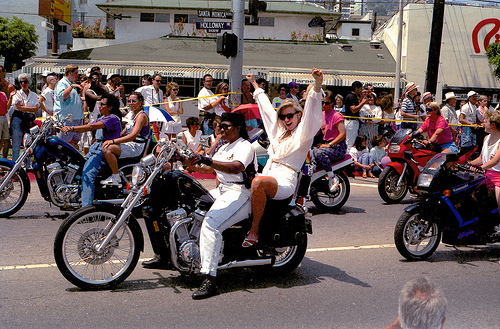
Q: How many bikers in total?
A: More than 10.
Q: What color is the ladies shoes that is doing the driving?
A: Black.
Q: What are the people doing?
A: Watching a parade.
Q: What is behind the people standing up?
A: Building.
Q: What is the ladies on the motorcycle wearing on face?
A: Sunglasses.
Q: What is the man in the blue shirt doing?
A: Watching the motorcycles go by.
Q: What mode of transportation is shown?
A: Motorcycles.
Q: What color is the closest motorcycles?
A: Black.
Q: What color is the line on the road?
A: White.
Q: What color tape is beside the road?
A: Yellow.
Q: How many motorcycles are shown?
A: 5.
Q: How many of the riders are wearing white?
A: 3.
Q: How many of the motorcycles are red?
A: 1.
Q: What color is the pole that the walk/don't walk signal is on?
A: Silver.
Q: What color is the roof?
A: Gray.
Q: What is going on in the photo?
A: Women riding motorcycles down a street.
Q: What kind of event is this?
A: A parade.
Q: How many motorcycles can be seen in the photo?
A: Five.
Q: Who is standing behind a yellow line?
A: People watching the parade.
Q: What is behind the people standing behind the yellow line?
A: A building.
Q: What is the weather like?
A: Sunny.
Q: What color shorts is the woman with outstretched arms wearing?
A: White.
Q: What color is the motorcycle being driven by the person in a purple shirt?
A: Blue.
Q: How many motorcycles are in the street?
A: 5.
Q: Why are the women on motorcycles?
A: In a parade.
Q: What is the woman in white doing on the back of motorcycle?
A: Raising both hands in the air.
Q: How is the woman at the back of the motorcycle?
A: Excited.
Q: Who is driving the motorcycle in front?
A: A woman.